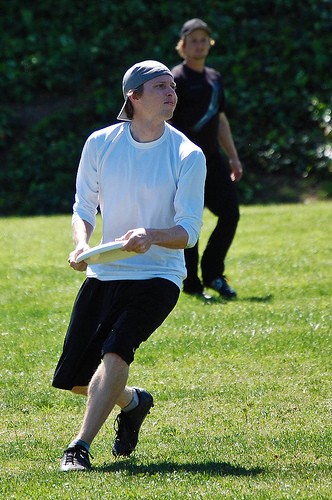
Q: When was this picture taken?
A: Daytime.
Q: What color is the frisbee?
A: White.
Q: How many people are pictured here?
A: Two.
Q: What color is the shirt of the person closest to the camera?
A: White.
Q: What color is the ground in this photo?
A: Green.